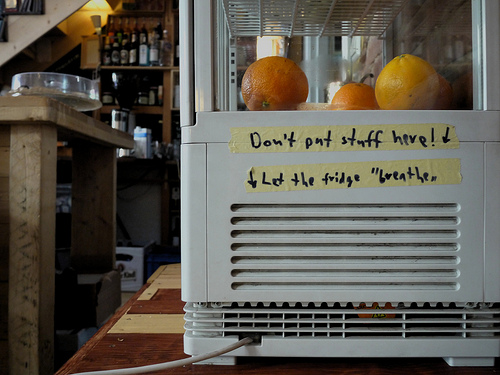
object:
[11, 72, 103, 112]
plastic tray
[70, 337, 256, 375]
cord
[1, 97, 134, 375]
table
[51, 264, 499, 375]
table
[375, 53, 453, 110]
lemon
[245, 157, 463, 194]
tape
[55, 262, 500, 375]
wooden table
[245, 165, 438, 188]
print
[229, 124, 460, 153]
tape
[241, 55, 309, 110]
orange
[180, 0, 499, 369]
container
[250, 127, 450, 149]
handwritten print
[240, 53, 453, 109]
oranges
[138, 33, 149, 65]
bottles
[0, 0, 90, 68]
staircase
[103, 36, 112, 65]
bottles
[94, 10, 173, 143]
shelf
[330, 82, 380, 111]
oranges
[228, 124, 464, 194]
tape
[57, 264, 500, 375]
table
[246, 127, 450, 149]
letters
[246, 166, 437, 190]
writing